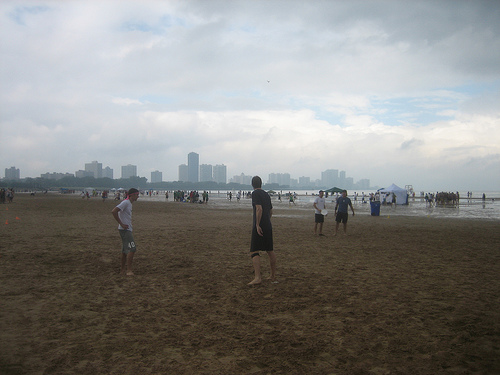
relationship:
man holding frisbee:
[312, 190, 327, 237] [320, 209, 329, 217]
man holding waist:
[113, 189, 139, 276] [118, 224, 134, 231]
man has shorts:
[246, 175, 277, 285] [249, 225, 275, 255]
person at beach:
[246, 175, 277, 285] [0, 184, 499, 374]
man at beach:
[312, 190, 327, 237] [0, 184, 499, 374]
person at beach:
[333, 190, 356, 230] [0, 184, 499, 374]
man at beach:
[113, 189, 139, 276] [0, 184, 499, 374]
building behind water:
[121, 164, 136, 179] [154, 192, 499, 203]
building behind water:
[177, 162, 189, 183] [154, 192, 499, 203]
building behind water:
[188, 152, 200, 185] [154, 192, 499, 203]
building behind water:
[198, 163, 213, 185] [154, 192, 499, 203]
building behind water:
[213, 166, 226, 185] [154, 192, 499, 203]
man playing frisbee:
[312, 190, 327, 237] [321, 209, 329, 215]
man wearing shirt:
[113, 189, 139, 276] [113, 198, 135, 231]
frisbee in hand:
[321, 209, 329, 215] [318, 207, 321, 213]